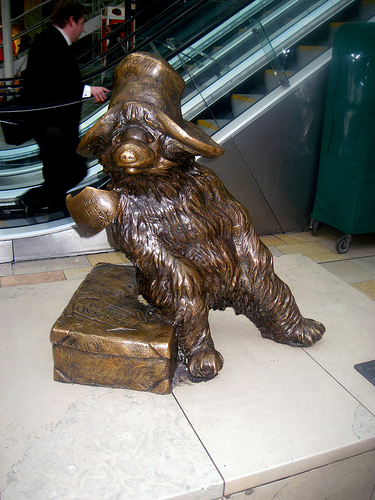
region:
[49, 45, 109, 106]
a white man's hand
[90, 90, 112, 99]
the finger's of a white man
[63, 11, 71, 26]
the ear of a white man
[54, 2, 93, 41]
the head of a white man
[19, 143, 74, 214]
the leg of a white man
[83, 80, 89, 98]
the white man's shirt hand sleeve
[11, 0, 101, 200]
a white man walking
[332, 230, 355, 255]
a wheel of a trolly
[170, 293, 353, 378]
the leg's of a seated statue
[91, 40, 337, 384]
a statue seated on a box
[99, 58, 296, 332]
this is a statue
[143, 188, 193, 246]
the statue is brown in color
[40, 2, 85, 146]
this is a man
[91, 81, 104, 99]
the man is light skinned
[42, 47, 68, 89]
this is a coat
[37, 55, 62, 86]
the coat is black in color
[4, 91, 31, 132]
this is a bag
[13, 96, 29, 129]
the bag is black in color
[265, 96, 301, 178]
this is the wall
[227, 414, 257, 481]
part of a floor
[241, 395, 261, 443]
par tof a floor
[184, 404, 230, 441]
part of a loine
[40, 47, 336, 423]
statue of bear and luggage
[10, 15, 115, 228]
person riding the escalator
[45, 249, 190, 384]
box part of statue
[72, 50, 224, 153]
hat on the statue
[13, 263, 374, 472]
stand statue rests on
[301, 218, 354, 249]
wheels on a cart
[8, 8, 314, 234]
escalator in the building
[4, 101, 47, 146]
bag on the man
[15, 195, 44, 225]
this is a shoe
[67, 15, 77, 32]
this is an era of a person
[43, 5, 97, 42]
this is a head of a person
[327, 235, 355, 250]
this is a wheel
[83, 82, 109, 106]
this is a hand of a person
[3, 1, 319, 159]
these are stairs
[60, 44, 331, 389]
this is a statue